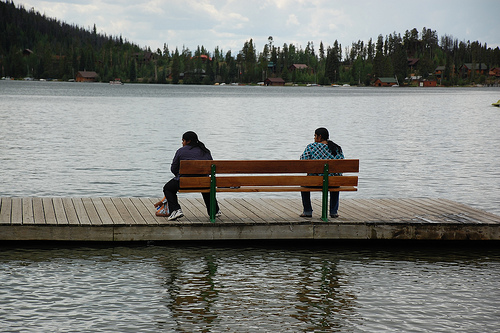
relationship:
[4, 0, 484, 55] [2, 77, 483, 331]
sky hanging above water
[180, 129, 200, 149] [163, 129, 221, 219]
head of woman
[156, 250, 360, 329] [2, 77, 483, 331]
reflection in water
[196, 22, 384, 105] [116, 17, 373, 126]
houses on shore line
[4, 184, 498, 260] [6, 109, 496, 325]
pier in water